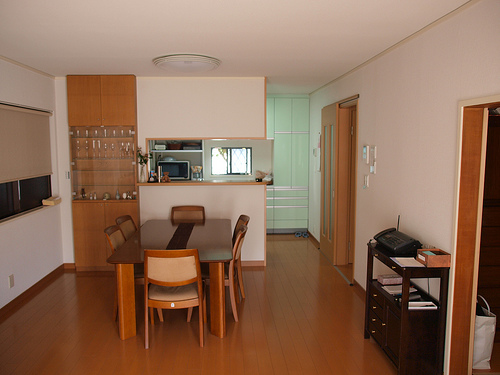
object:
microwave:
[157, 160, 191, 180]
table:
[106, 218, 233, 340]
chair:
[143, 249, 206, 349]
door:
[319, 104, 338, 267]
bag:
[472, 293, 498, 371]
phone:
[374, 227, 397, 239]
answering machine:
[372, 213, 423, 257]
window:
[211, 147, 253, 176]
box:
[416, 247, 452, 267]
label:
[418, 254, 426, 262]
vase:
[138, 165, 147, 183]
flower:
[137, 146, 148, 157]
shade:
[1, 100, 52, 184]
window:
[0, 99, 53, 221]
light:
[152, 53, 221, 75]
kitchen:
[132, 75, 327, 266]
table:
[363, 236, 449, 375]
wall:
[306, 0, 499, 375]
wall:
[267, 94, 310, 235]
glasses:
[82, 140, 91, 161]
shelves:
[72, 155, 136, 164]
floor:
[1, 233, 499, 375]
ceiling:
[0, 2, 474, 96]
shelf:
[366, 234, 451, 272]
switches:
[363, 174, 369, 189]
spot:
[170, 303, 176, 308]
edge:
[311, 0, 476, 94]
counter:
[137, 179, 268, 187]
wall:
[54, 77, 267, 269]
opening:
[145, 139, 267, 184]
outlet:
[7, 273, 16, 288]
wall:
[0, 58, 63, 318]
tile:
[273, 206, 309, 221]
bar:
[73, 184, 137, 200]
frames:
[362, 145, 370, 165]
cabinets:
[68, 126, 139, 203]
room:
[0, 1, 499, 375]